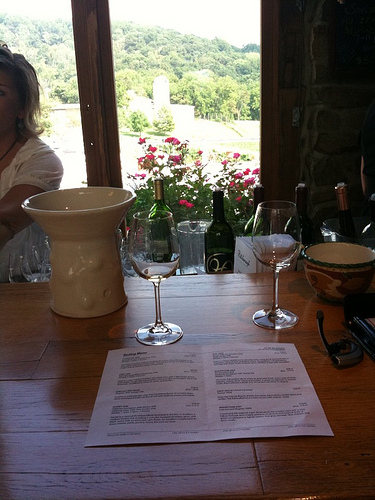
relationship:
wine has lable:
[198, 189, 238, 270] [207, 247, 241, 276]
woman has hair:
[8, 58, 73, 219] [14, 68, 57, 133]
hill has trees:
[148, 24, 237, 130] [162, 54, 200, 76]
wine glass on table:
[238, 203, 309, 321] [18, 341, 100, 454]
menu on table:
[100, 325, 329, 469] [18, 341, 100, 454]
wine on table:
[198, 189, 238, 270] [18, 341, 100, 454]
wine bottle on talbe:
[141, 172, 189, 265] [198, 271, 243, 316]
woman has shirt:
[8, 58, 73, 219] [0, 149, 81, 182]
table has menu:
[18, 341, 100, 454] [100, 325, 329, 469]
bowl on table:
[301, 237, 367, 300] [18, 341, 100, 454]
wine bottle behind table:
[141, 172, 189, 265] [18, 341, 100, 454]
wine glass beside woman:
[238, 203, 309, 321] [8, 58, 73, 219]